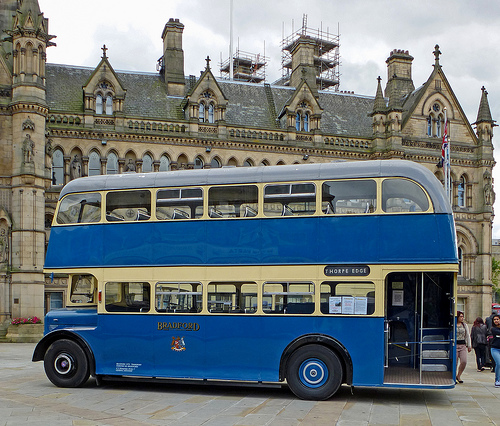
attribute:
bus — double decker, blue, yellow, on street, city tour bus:
[26, 155, 468, 402]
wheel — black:
[282, 343, 342, 401]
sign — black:
[322, 265, 372, 278]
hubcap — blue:
[297, 357, 329, 389]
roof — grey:
[56, 156, 454, 213]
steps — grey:
[417, 326, 454, 372]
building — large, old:
[1, 0, 496, 349]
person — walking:
[449, 310, 473, 385]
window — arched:
[92, 91, 115, 118]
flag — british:
[435, 119, 451, 178]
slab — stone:
[397, 412, 431, 425]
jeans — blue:
[487, 347, 499, 383]